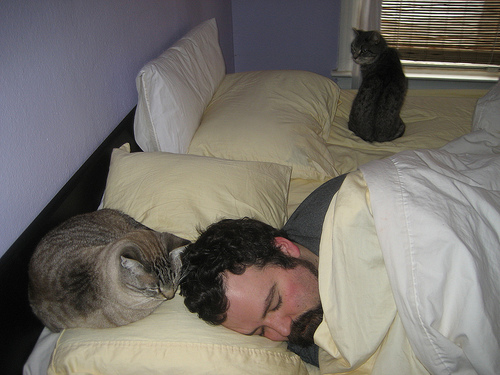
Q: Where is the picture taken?
A: A bedroom.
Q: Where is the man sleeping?
A: A bed.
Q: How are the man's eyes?
A: Closed.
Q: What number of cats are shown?
A: Two.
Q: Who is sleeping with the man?
A: Cats.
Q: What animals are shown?
A: Cats.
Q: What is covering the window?
A: A blind.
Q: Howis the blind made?
A: Of bamboo.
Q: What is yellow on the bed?
A: Sheets.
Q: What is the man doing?
A: Sleeping.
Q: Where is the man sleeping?
A: On a bed.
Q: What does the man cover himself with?
A: A blanket.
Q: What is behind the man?
A: Another cat.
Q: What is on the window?
A: Blinds.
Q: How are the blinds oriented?
A: The blinds are down.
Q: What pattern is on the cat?
A: Stripes.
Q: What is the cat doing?
A: Sitting on the bed.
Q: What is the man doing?
A: Sleeping.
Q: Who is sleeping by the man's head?
A: A cat.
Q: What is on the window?
A: Blinds.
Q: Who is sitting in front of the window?
A: A cat.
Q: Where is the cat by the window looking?
A: Over its shoulder.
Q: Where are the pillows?
A: On the bed.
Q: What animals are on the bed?
A: Two cats.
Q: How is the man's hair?
A: Curly.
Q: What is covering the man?
A: A blanket.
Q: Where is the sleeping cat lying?
A: On a pillow next to the man.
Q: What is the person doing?
A: Sleeping.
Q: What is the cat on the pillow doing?
A: Sleeping.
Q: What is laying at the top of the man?
A: Cat.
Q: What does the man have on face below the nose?
A: Mustache.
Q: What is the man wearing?
A: Gray shirt.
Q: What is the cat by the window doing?
A: Sitting.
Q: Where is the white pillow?
A: Up against the wall.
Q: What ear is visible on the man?
A: Right one.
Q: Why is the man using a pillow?
A: Sleeping comfort.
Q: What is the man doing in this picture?
A: Sleeping.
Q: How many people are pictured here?
A: One.